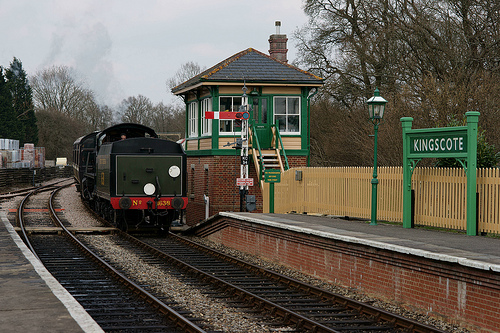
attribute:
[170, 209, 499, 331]
platform — gray, concrete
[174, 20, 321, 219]
train station — green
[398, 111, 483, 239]
sign — green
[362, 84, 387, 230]
light fixture — green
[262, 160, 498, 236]
fence — dark yellow